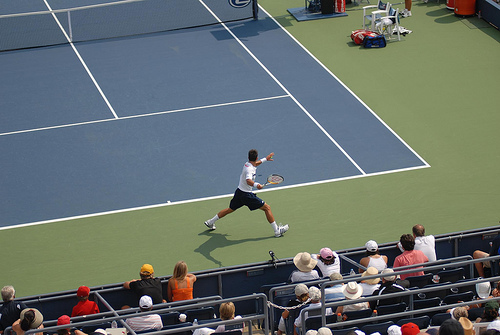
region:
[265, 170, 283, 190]
Tennis racquet in man's hand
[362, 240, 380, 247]
White hat on person's head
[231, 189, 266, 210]
Black shorts on tennis player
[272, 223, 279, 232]
White sock on tennis player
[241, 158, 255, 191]
White shirt on tennis player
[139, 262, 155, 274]
Yellow cap on man's head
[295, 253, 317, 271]
Tan straw hat on lady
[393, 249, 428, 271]
Pink shirt on spectator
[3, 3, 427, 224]
White lines on tennis court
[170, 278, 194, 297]
Orange tank top on girl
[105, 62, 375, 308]
a man playing tennis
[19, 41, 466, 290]
a man on a tennis court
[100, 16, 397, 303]
a tennis player on court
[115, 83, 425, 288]
a tennis player on a tennis court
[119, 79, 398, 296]
a player in a court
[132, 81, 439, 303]
player on a court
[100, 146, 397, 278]
player on a tennis court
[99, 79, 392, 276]
a man holding a racket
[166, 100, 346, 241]
a man holding a tennis racket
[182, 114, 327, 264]
a man running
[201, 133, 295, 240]
man playing tennis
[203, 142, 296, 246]
man ready to hit tennis ball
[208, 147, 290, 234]
man holding tennis racket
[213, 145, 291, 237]
man holding tennis racket with right hand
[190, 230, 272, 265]
shadow of man playing tennis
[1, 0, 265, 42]
tennis net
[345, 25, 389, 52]
set of sports bag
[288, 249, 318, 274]
person wearing a sun hat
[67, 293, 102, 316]
person wearing red shirt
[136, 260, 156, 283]
person wearing orange hat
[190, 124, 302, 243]
guy playing tennis on the court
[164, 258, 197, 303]
woman in a orange tanktop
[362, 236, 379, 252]
white cap on the man's head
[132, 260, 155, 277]
yellow hat of the guy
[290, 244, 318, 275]
tan straw hat on the person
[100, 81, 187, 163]
white lines on the court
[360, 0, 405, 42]
blue and white chairs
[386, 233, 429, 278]
woman wearing pink shirt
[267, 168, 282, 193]
tennis racket in the mans hand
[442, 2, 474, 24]
red and white drink coolers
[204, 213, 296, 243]
the tennis player's sneakers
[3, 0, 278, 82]
the tennis net on the court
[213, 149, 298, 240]
the tennis player in the picture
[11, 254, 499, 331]
the fans behind the tennis player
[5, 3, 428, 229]
the blue tennis court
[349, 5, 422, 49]
the tennis player's chairs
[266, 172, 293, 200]
the tennis racket the player is using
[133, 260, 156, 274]
the guy's orange hat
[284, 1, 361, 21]
the line judge's chair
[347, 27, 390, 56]
the tennis player's bags